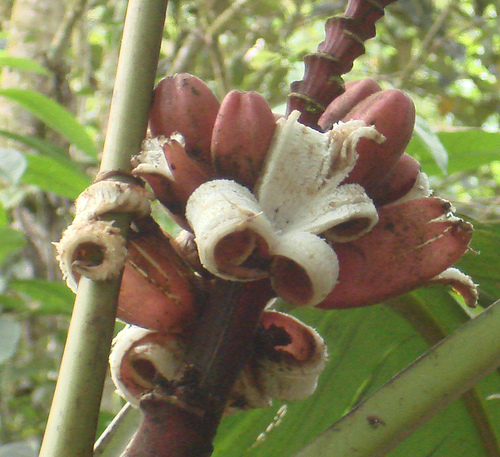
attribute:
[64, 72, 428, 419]
bananas — grow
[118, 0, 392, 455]
stalk — red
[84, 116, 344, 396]
bananas — red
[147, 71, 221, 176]
banana — red, open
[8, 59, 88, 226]
leaf — green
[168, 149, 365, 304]
peels — purple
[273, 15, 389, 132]
stalk — red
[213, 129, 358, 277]
peel — open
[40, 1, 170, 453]
stem — green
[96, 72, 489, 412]
bananas — red, open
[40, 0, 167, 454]
stalk — green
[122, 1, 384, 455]
stem — purple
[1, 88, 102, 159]
leaf — large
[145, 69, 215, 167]
banana — bad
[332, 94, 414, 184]
banana — bad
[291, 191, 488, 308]
banana — red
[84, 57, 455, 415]
bananas — open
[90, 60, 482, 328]
bananas — open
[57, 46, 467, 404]
bananas — red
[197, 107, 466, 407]
banana — ripened